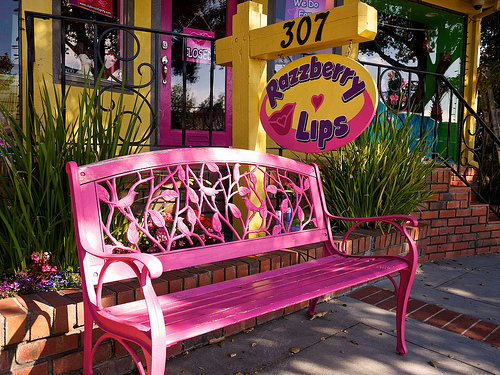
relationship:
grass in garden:
[0, 106, 143, 278] [4, 110, 412, 260]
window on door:
[171, 0, 224, 130] [154, 3, 238, 167]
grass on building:
[0, 106, 143, 278] [2, 1, 498, 255]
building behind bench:
[4, 3, 237, 145] [60, 144, 420, 374]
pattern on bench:
[94, 160, 323, 264] [60, 144, 420, 374]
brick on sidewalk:
[349, 280, 499, 351] [184, 276, 489, 374]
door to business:
[152, 7, 237, 143] [0, 4, 499, 258]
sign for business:
[230, 5, 385, 240] [10, 10, 477, 239]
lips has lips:
[263, 102, 295, 134] [267, 102, 295, 135]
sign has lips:
[230, 5, 385, 240] [267, 102, 295, 135]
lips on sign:
[267, 102, 295, 135] [230, 5, 385, 240]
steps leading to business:
[437, 151, 495, 248] [41, 8, 484, 258]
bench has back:
[60, 144, 420, 374] [75, 147, 330, 287]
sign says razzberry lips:
[230, 5, 385, 240] [269, 59, 366, 150]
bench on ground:
[60, 144, 420, 374] [64, 245, 499, 370]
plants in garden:
[331, 80, 446, 179] [66, 23, 486, 233]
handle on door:
[156, 40, 177, 85] [156, 4, 229, 150]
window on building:
[47, 8, 141, 85] [20, 8, 481, 195]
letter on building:
[294, 109, 310, 140] [2, 1, 498, 255]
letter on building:
[294, 109, 310, 140] [10, 7, 484, 239]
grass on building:
[0, 106, 143, 278] [2, 0, 499, 375]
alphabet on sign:
[264, 77, 285, 107] [230, 5, 385, 240]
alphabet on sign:
[293, 111, 362, 146] [230, 5, 385, 240]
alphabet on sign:
[266, 71, 376, 143] [230, 5, 385, 240]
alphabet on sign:
[293, 110, 350, 149] [230, 5, 385, 240]